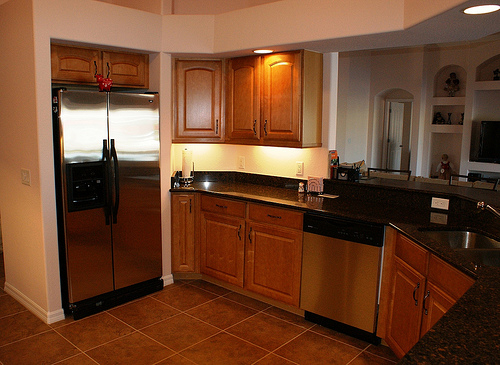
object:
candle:
[181, 147, 192, 177]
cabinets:
[167, 49, 307, 145]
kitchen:
[4, 1, 500, 360]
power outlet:
[296, 161, 304, 176]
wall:
[171, 5, 297, 51]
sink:
[418, 223, 498, 249]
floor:
[6, 287, 393, 358]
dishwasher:
[296, 210, 382, 341]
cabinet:
[250, 194, 379, 338]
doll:
[436, 153, 457, 180]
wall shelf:
[334, 52, 415, 176]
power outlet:
[430, 197, 449, 210]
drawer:
[200, 195, 247, 218]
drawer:
[248, 203, 303, 230]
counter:
[172, 167, 499, 279]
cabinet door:
[199, 197, 247, 288]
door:
[112, 92, 159, 309]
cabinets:
[170, 56, 225, 141]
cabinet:
[53, 45, 100, 83]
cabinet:
[103, 49, 150, 88]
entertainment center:
[469, 119, 499, 163]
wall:
[338, 38, 378, 160]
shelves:
[425, 63, 472, 179]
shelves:
[467, 54, 498, 162]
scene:
[9, 3, 494, 356]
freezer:
[61, 86, 163, 317]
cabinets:
[171, 193, 201, 281]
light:
[252, 49, 273, 54]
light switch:
[20, 168, 32, 187]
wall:
[3, 0, 26, 295]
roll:
[181, 147, 192, 177]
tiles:
[2, 313, 96, 360]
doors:
[55, 77, 159, 318]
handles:
[101, 138, 121, 225]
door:
[56, 81, 116, 322]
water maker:
[65, 161, 103, 212]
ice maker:
[66, 160, 105, 214]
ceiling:
[35, 0, 500, 52]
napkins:
[306, 177, 324, 193]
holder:
[306, 175, 323, 195]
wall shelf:
[362, 54, 500, 176]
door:
[383, 100, 413, 169]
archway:
[375, 88, 415, 169]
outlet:
[239, 155, 245, 169]